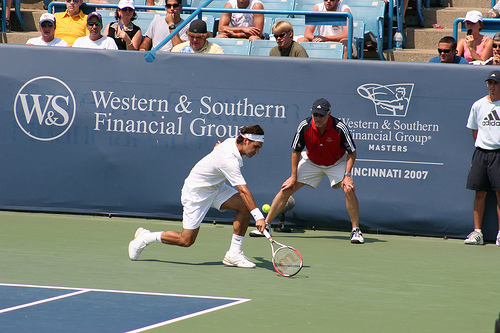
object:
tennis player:
[127, 122, 305, 278]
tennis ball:
[261, 203, 273, 215]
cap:
[309, 97, 331, 116]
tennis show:
[128, 226, 157, 261]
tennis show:
[220, 247, 255, 269]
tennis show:
[463, 230, 483, 247]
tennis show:
[348, 226, 365, 243]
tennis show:
[248, 225, 270, 237]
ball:
[261, 201, 276, 214]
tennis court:
[0, 283, 252, 331]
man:
[129, 116, 266, 272]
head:
[236, 125, 268, 159]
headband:
[240, 133, 267, 142]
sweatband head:
[234, 123, 265, 158]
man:
[250, 96, 364, 245]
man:
[463, 70, 500, 245]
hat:
[482, 65, 499, 84]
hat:
[308, 97, 331, 116]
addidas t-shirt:
[468, 97, 499, 151]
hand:
[250, 213, 274, 232]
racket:
[262, 223, 304, 278]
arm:
[237, 184, 262, 220]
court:
[0, 210, 498, 332]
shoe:
[221, 249, 256, 267]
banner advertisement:
[1, 44, 498, 240]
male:
[127, 124, 302, 278]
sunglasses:
[270, 31, 290, 39]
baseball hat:
[309, 96, 331, 115]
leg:
[128, 186, 209, 260]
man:
[127, 124, 269, 268]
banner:
[1, 45, 498, 242]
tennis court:
[0, 210, 499, 329]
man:
[26, 9, 69, 48]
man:
[73, 13, 120, 50]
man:
[171, 19, 226, 54]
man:
[267, 20, 310, 58]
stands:
[3, 1, 499, 67]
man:
[429, 35, 470, 65]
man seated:
[25, 12, 69, 47]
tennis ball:
[262, 202, 272, 213]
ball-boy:
[467, 71, 500, 246]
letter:
[90, 87, 111, 109]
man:
[249, 98, 368, 245]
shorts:
[295, 152, 355, 188]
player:
[128, 124, 303, 276]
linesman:
[253, 97, 365, 243]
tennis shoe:
[126, 227, 257, 269]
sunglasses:
[436, 47, 451, 54]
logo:
[15, 75, 79, 141]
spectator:
[75, 12, 121, 49]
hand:
[253, 220, 272, 235]